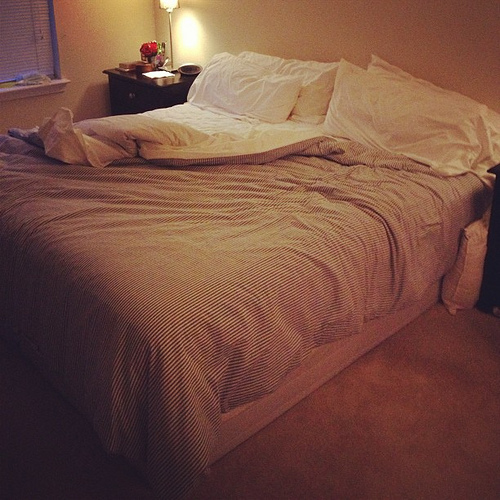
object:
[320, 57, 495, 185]
white pillow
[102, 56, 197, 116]
nightstand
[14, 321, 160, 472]
wall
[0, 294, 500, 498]
floor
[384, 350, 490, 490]
carpet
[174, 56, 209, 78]
clock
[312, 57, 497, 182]
pillow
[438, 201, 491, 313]
pillow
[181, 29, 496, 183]
pillows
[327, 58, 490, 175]
pillows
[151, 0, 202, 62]
light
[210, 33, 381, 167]
pillows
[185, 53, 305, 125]
pillow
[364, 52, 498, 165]
pillow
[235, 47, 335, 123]
pillow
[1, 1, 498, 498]
building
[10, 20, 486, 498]
bedroom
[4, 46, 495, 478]
bed